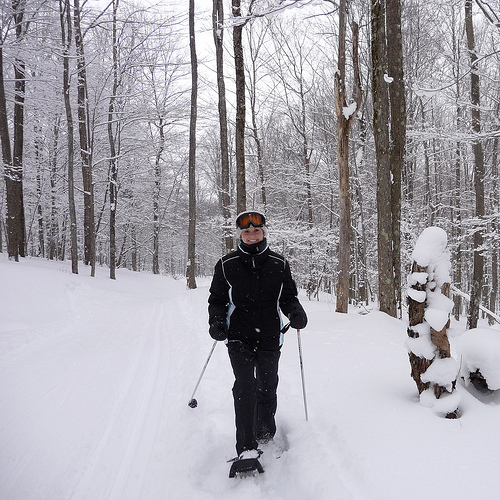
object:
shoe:
[225, 447, 262, 480]